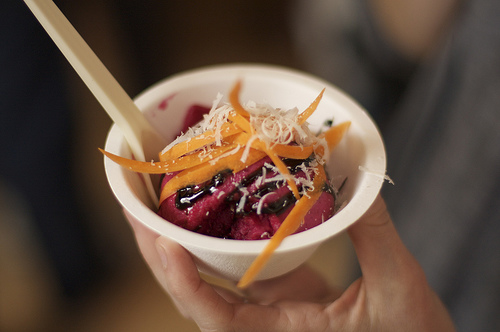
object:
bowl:
[102, 62, 386, 282]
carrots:
[99, 140, 237, 173]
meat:
[277, 206, 304, 231]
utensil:
[23, 0, 169, 211]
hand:
[122, 201, 457, 332]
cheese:
[205, 102, 226, 120]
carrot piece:
[236, 165, 326, 287]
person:
[290, 0, 498, 332]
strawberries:
[179, 203, 208, 230]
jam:
[174, 191, 211, 207]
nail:
[154, 243, 168, 264]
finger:
[154, 236, 286, 332]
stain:
[154, 93, 175, 113]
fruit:
[97, 79, 348, 289]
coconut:
[226, 170, 251, 184]